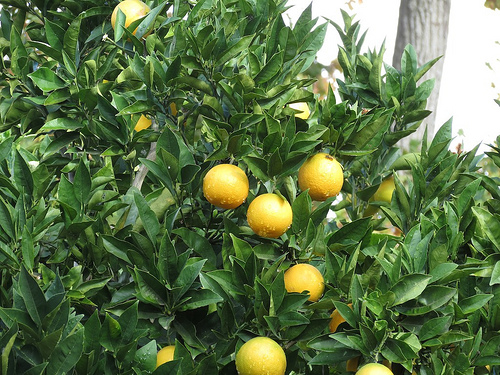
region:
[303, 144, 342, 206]
a yellow orange fruit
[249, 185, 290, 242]
a yellow orange fruit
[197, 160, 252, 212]
a yellow orange fruit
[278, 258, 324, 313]
a yellow orange fruit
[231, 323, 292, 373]
a yellow orange fruit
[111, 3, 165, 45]
a yellow orange fruit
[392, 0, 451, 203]
a grey tree trunk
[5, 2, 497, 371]
many green leaves on a fruit tree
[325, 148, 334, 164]
a dark shadow on an orange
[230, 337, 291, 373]
a greenish orance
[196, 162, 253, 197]
lemons on a tree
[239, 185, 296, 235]
lemons on a tree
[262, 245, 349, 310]
lemons on a tree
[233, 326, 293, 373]
lemons on a tree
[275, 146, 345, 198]
lemons on a tree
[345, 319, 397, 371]
lemons on a tree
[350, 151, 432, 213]
lemons on a tree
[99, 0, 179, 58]
lemons on a tree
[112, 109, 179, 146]
lemons on a tree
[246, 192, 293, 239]
a round lemon fruit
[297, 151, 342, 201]
a round lemon fruit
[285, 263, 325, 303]
a round lemon fruit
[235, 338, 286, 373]
a round lemon fruit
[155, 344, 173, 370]
a round lemon fruit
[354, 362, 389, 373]
a round lemon fruit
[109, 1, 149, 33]
a round lemon fruita round lemon fruit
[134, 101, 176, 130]
a round lemon fruit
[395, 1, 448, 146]
a grey tree trunk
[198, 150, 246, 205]
this is a lemon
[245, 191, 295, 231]
the lemon is very round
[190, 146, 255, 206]
this lemon is spherical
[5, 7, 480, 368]
this is a lemon tree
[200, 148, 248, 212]
a yellow lemon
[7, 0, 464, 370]
lemons on branches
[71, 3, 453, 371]
lemons in a tree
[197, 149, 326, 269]
there are water droplets on these lemons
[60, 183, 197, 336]
these leaves are green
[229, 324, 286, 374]
this lemon is still a little green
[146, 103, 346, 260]
lemons on a tree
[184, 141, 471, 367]
lemons on a branch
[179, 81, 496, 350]
yellow lemons on the tree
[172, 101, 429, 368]
yellow lemons ont he branch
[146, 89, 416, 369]
leaves on a tree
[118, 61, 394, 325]
leaves on the branch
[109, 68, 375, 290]
green leaves on the tree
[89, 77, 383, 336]
green leaves on a branch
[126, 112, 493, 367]
a tree with lemons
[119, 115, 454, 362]
a tree with yellow lemons